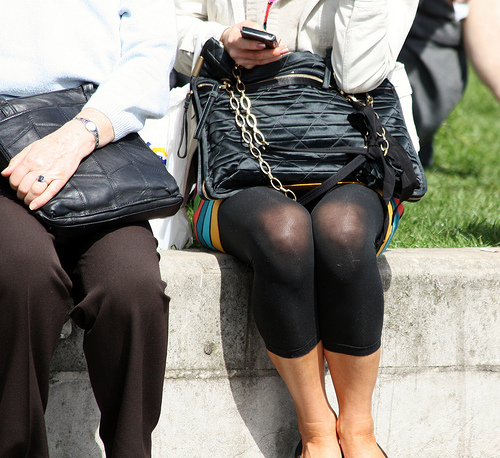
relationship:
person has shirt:
[153, 0, 424, 458] [142, 2, 415, 102]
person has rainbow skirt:
[153, 0, 424, 458] [187, 178, 412, 250]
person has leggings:
[153, 0, 424, 458] [221, 180, 385, 358]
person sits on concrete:
[153, 0, 424, 458] [4, 225, 496, 455]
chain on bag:
[215, 73, 390, 191] [190, 62, 428, 201]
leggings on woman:
[215, 186, 393, 382] [135, 4, 455, 456]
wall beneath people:
[5, 250, 498, 454] [6, 3, 460, 453]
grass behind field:
[381, 215, 498, 247] [385, 62, 498, 247]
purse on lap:
[178, 62, 309, 211] [194, 114, 464, 324]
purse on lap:
[2, 81, 184, 233] [0, 187, 160, 280]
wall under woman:
[5, 250, 498, 454] [198, 5, 423, 452]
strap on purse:
[222, 84, 409, 204] [164, 43, 431, 204]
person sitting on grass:
[177, 3, 444, 457] [442, 129, 499, 237]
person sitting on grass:
[3, 0, 183, 457] [442, 129, 499, 237]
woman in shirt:
[4, 0, 188, 457] [0, 0, 190, 138]